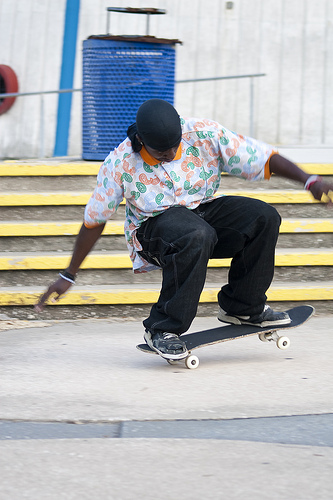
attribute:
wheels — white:
[262, 334, 294, 351]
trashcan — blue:
[81, 30, 207, 149]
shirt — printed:
[94, 130, 285, 211]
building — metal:
[24, 7, 326, 130]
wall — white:
[167, 7, 317, 150]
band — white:
[58, 274, 77, 286]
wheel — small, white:
[185, 349, 214, 381]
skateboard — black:
[149, 282, 323, 354]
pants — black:
[164, 187, 302, 369]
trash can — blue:
[78, 29, 173, 157]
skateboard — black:
[138, 288, 323, 341]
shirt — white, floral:
[81, 135, 275, 228]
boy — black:
[58, 96, 329, 374]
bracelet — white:
[57, 270, 76, 288]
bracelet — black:
[59, 265, 78, 279]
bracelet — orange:
[305, 174, 321, 190]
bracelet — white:
[304, 171, 321, 188]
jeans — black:
[137, 194, 285, 334]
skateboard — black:
[132, 302, 318, 360]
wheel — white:
[274, 335, 292, 347]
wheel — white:
[256, 325, 276, 341]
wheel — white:
[186, 350, 202, 369]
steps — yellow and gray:
[0, 158, 332, 304]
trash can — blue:
[81, 7, 185, 161]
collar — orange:
[124, 121, 186, 170]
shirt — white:
[81, 115, 281, 273]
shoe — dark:
[216, 305, 294, 331]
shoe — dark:
[142, 324, 192, 358]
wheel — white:
[274, 331, 295, 350]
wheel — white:
[256, 326, 280, 342]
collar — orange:
[135, 138, 188, 165]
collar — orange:
[135, 134, 188, 165]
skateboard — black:
[133, 302, 315, 354]